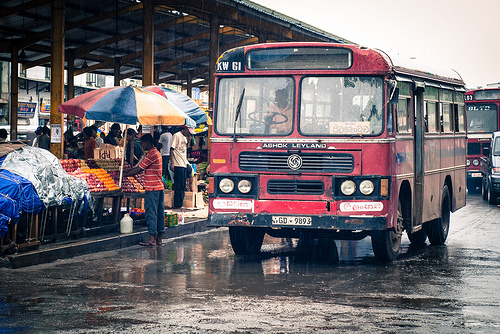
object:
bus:
[206, 41, 468, 261]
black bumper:
[206, 213, 387, 231]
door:
[413, 83, 424, 231]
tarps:
[0, 145, 96, 236]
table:
[0, 197, 141, 241]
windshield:
[215, 74, 384, 136]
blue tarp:
[0, 166, 42, 238]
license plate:
[271, 216, 311, 226]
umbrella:
[139, 83, 213, 134]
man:
[169, 129, 192, 213]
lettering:
[273, 217, 311, 225]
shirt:
[158, 132, 173, 156]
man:
[123, 128, 146, 168]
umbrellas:
[57, 85, 196, 190]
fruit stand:
[0, 191, 145, 253]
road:
[1, 214, 500, 334]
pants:
[144, 189, 166, 235]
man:
[114, 133, 165, 247]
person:
[83, 126, 98, 160]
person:
[103, 123, 121, 146]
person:
[34, 113, 56, 140]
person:
[63, 130, 79, 148]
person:
[38, 126, 51, 151]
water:
[83, 229, 330, 294]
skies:
[268, 0, 497, 79]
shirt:
[139, 147, 166, 192]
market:
[0, 0, 209, 272]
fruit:
[59, 158, 119, 192]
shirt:
[170, 131, 188, 168]